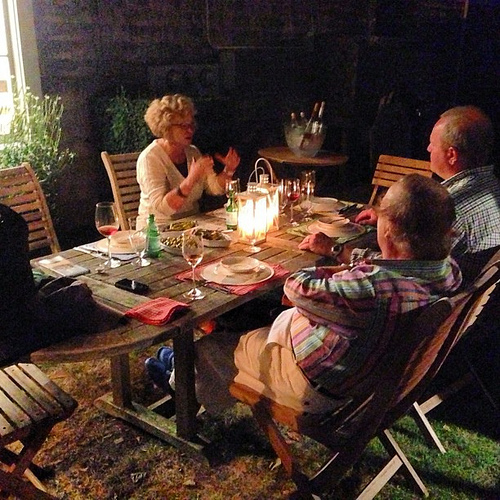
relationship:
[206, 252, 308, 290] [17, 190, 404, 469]
plate on a table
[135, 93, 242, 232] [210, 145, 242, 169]
people has hand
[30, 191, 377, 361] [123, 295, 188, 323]
table has napkin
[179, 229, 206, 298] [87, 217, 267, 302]
glass on table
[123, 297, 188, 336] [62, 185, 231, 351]
napkin on table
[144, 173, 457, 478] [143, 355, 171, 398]
man wearing shoe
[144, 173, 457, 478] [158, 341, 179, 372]
man wearing shoe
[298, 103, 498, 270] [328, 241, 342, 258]
man wearing watch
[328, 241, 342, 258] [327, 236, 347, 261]
watch on wrist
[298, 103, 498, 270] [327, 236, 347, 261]
man has wrist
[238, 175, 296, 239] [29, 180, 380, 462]
glass on table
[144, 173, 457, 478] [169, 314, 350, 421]
man wearing pants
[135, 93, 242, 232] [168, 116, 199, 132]
people wearing glasses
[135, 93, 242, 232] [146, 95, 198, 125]
people has hair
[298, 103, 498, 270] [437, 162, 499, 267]
man wearing shirt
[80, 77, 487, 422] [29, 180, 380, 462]
people sitting at table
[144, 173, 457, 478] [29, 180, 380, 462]
man sitting at table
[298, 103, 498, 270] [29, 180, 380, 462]
man sitting at table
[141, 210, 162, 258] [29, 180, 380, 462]
glass bottle on table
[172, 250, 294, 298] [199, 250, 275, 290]
placemat under plate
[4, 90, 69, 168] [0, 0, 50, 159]
plant at window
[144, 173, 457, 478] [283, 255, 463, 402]
man wearing shirt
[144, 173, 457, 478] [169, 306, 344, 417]
man wearing pants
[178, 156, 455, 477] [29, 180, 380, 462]
man sitting at table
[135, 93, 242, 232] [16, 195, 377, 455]
people sitting at table